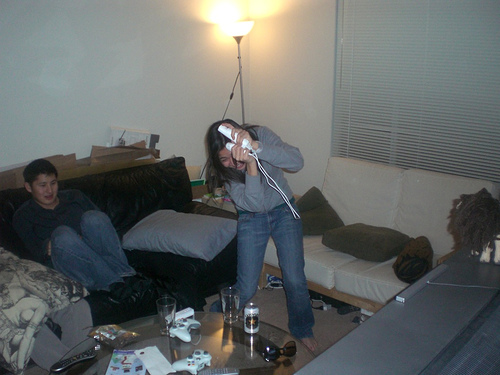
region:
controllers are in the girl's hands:
[203, 115, 306, 209]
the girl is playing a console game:
[133, 122, 466, 370]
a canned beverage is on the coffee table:
[242, 303, 260, 335]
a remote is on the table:
[47, 346, 99, 373]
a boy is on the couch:
[8, 148, 193, 323]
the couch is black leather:
[23, 155, 238, 337]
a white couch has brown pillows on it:
[271, 151, 499, 303]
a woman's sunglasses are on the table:
[256, 338, 301, 365]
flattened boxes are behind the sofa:
[0, 130, 192, 193]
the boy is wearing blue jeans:
[48, 208, 129, 288]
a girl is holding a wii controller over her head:
[197, 113, 327, 359]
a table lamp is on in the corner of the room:
[217, 15, 255, 125]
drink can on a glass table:
[243, 300, 262, 335]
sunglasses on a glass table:
[261, 339, 298, 363]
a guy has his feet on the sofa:
[11, 153, 161, 311]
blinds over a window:
[328, 3, 498, 186]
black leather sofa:
[4, 155, 244, 322]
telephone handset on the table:
[45, 343, 102, 373]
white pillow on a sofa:
[114, 204, 241, 265]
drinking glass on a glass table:
[218, 283, 242, 325]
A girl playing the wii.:
[206, 120, 320, 350]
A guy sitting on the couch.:
[14, 152, 161, 308]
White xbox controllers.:
[166, 315, 214, 373]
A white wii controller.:
[217, 122, 254, 164]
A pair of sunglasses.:
[256, 340, 301, 362]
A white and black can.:
[245, 302, 261, 334]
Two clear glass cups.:
[154, 284, 241, 331]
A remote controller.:
[52, 348, 97, 372]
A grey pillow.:
[120, 207, 237, 259]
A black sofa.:
[1, 147, 248, 327]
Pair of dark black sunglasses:
[261, 339, 298, 361]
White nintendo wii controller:
[218, 125, 253, 154]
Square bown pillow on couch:
[323, 218, 413, 263]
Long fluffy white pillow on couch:
[120, 208, 235, 261]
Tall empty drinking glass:
[218, 285, 241, 323]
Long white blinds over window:
[331, 85, 498, 182]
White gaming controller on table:
[171, 348, 211, 374]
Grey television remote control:
[50, 348, 98, 373]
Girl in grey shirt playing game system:
[204, 113, 319, 355]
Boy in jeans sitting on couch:
[12, 158, 151, 305]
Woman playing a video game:
[203, 114, 328, 350]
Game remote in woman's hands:
[216, 119, 266, 177]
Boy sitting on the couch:
[4, 162, 153, 314]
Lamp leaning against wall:
[206, 17, 271, 127]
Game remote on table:
[171, 342, 212, 372]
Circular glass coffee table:
[41, 306, 322, 373]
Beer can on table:
[235, 299, 261, 336]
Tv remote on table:
[49, 345, 98, 372]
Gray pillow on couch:
[118, 192, 238, 263]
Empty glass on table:
[214, 282, 240, 328]